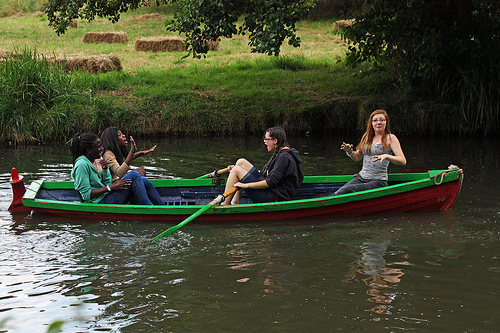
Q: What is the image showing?
A: It is showing a field.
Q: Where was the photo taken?
A: It was taken at the field.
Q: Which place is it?
A: It is a field.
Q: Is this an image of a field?
A: Yes, it is showing a field.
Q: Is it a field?
A: Yes, it is a field.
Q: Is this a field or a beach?
A: It is a field.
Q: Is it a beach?
A: No, it is a field.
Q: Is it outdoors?
A: Yes, it is outdoors.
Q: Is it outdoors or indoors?
A: It is outdoors.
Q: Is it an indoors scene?
A: No, it is outdoors.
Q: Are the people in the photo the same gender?
A: Yes, all the people are female.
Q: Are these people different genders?
A: No, all the people are female.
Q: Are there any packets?
A: No, there are no packets.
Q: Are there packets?
A: No, there are no packets.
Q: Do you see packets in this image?
A: No, there are no packets.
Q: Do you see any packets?
A: No, there are no packets.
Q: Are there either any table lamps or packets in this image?
A: No, there are no packets or table lamps.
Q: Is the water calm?
A: Yes, the water is calm.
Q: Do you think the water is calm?
A: Yes, the water is calm.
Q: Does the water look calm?
A: Yes, the water is calm.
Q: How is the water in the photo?
A: The water is calm.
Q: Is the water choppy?
A: No, the water is calm.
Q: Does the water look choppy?
A: No, the water is calm.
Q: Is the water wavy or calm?
A: The water is calm.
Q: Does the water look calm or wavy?
A: The water is calm.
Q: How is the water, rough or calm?
A: The water is calm.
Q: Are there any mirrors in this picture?
A: No, there are no mirrors.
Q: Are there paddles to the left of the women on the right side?
A: Yes, there is a paddle to the left of the women.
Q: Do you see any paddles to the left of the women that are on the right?
A: Yes, there is a paddle to the left of the women.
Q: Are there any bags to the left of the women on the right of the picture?
A: No, there is a paddle to the left of the women.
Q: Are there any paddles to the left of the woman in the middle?
A: Yes, there is a paddle to the left of the woman.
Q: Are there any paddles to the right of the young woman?
A: No, the paddle is to the left of the woman.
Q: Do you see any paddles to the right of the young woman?
A: No, the paddle is to the left of the woman.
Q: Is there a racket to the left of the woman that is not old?
A: No, there is a paddle to the left of the woman.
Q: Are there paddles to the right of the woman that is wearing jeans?
A: Yes, there is a paddle to the right of the woman.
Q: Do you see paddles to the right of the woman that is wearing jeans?
A: Yes, there is a paddle to the right of the woman.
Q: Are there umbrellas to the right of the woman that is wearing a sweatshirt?
A: No, there is a paddle to the right of the woman.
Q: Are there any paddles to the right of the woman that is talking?
A: Yes, there is a paddle to the right of the woman.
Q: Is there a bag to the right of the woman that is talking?
A: No, there is a paddle to the right of the woman.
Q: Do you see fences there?
A: No, there are no fences.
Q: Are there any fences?
A: No, there are no fences.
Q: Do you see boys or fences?
A: No, there are no fences or boys.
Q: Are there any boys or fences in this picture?
A: No, there are no fences or boys.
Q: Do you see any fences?
A: No, there are no fences.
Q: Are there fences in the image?
A: No, there are no fences.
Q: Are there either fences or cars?
A: No, there are no fences or cars.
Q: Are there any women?
A: Yes, there are women.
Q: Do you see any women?
A: Yes, there are women.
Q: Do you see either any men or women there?
A: Yes, there are women.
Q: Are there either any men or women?
A: Yes, there are women.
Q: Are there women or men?
A: Yes, there are women.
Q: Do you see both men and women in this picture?
A: No, there are women but no men.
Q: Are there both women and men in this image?
A: No, there are women but no men.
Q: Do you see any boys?
A: No, there are no boys.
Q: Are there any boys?
A: No, there are no boys.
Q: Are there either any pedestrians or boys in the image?
A: No, there are no boys or pedestrians.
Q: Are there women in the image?
A: Yes, there is a woman.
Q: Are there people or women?
A: Yes, there is a woman.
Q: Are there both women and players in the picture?
A: No, there is a woman but no players.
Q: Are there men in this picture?
A: No, there are no men.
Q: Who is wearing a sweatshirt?
A: The woman is wearing a sweatshirt.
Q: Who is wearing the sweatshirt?
A: The woman is wearing a sweatshirt.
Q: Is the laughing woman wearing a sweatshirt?
A: Yes, the woman is wearing a sweatshirt.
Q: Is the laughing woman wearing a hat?
A: No, the woman is wearing a sweatshirt.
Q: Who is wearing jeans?
A: The woman is wearing jeans.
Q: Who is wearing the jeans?
A: The woman is wearing jeans.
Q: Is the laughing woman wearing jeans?
A: Yes, the woman is wearing jeans.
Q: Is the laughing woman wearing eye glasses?
A: No, the woman is wearing jeans.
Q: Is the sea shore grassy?
A: Yes, the sea shore is grassy.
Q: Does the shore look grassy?
A: Yes, the shore is grassy.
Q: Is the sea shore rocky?
A: No, the sea shore is grassy.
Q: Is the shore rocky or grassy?
A: The shore is grassy.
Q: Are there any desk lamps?
A: No, there are no desk lamps.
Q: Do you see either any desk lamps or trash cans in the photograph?
A: No, there are no desk lamps or trash cans.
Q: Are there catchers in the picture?
A: No, there are no catchers.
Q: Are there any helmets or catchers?
A: No, there are no catchers or helmets.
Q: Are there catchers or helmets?
A: No, there are no catchers or helmets.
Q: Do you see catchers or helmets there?
A: No, there are no catchers or helmets.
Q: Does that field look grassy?
A: Yes, the field is grassy.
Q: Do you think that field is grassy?
A: Yes, the field is grassy.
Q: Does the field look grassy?
A: Yes, the field is grassy.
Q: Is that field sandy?
A: No, the field is grassy.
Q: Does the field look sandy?
A: No, the field is grassy.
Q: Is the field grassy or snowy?
A: The field is grassy.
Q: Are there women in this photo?
A: Yes, there is a woman.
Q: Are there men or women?
A: Yes, there is a woman.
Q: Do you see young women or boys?
A: Yes, there is a young woman.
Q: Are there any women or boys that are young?
A: Yes, the woman is young.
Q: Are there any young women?
A: Yes, there is a young woman.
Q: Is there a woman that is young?
A: Yes, there is a woman that is young.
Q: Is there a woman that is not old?
A: Yes, there is an young woman.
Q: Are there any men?
A: No, there are no men.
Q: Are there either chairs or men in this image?
A: No, there are no men or chairs.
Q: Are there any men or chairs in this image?
A: No, there are no men or chairs.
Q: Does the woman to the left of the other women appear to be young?
A: Yes, the woman is young.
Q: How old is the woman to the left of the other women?
A: The woman is young.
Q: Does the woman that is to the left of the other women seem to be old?
A: No, the woman is young.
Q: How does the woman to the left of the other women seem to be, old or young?
A: The woman is young.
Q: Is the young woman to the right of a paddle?
A: Yes, the woman is to the right of a paddle.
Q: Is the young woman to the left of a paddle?
A: No, the woman is to the right of a paddle.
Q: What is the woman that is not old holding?
A: The woman is holding the oar.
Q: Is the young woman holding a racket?
A: No, the woman is holding the oar.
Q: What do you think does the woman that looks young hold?
A: The woman holds the oar.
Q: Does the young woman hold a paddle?
A: Yes, the woman holds a paddle.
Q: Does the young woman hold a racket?
A: No, the woman holds a paddle.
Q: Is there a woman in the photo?
A: Yes, there is a woman.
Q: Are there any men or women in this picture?
A: Yes, there is a woman.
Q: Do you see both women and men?
A: No, there is a woman but no men.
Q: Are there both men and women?
A: No, there is a woman but no men.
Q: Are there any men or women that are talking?
A: Yes, the woman is talking.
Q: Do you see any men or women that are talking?
A: Yes, the woman is talking.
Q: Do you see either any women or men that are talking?
A: Yes, the woman is talking.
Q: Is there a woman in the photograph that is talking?
A: Yes, there is a woman that is talking.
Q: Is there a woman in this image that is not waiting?
A: Yes, there is a woman that is talking.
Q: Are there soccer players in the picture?
A: No, there are no soccer players.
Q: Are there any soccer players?
A: No, there are no soccer players.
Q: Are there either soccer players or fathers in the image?
A: No, there are no soccer players or fathers.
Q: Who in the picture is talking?
A: The woman is talking.